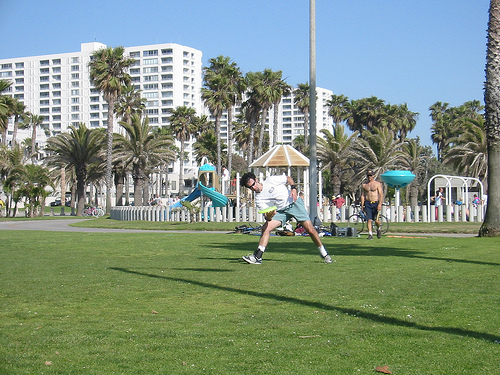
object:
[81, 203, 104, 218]
bicycle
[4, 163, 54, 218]
tree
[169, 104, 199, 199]
tree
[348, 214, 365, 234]
wheel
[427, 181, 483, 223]
black outfit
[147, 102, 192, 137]
wall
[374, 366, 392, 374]
brown leaf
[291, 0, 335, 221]
street light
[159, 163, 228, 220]
board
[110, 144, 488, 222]
playground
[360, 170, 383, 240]
man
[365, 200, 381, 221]
blue shorts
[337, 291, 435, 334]
ground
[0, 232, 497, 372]
green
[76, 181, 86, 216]
trunks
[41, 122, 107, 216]
palm trees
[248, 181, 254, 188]
sunglasses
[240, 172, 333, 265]
man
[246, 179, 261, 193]
face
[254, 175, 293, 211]
shirt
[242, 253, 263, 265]
shoe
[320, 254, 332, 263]
shoe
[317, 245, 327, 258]
socks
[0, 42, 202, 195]
building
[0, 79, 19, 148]
trees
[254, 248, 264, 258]
ankle brace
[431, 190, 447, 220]
people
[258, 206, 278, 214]
frisbee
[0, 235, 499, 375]
grass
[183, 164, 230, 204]
slides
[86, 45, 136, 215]
palm tree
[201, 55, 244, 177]
palm tree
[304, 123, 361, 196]
palm tree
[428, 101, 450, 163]
palm tree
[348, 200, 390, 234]
bicycle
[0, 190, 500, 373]
park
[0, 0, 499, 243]
background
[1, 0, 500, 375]
photo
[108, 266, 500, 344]
shadow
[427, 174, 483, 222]
swingset